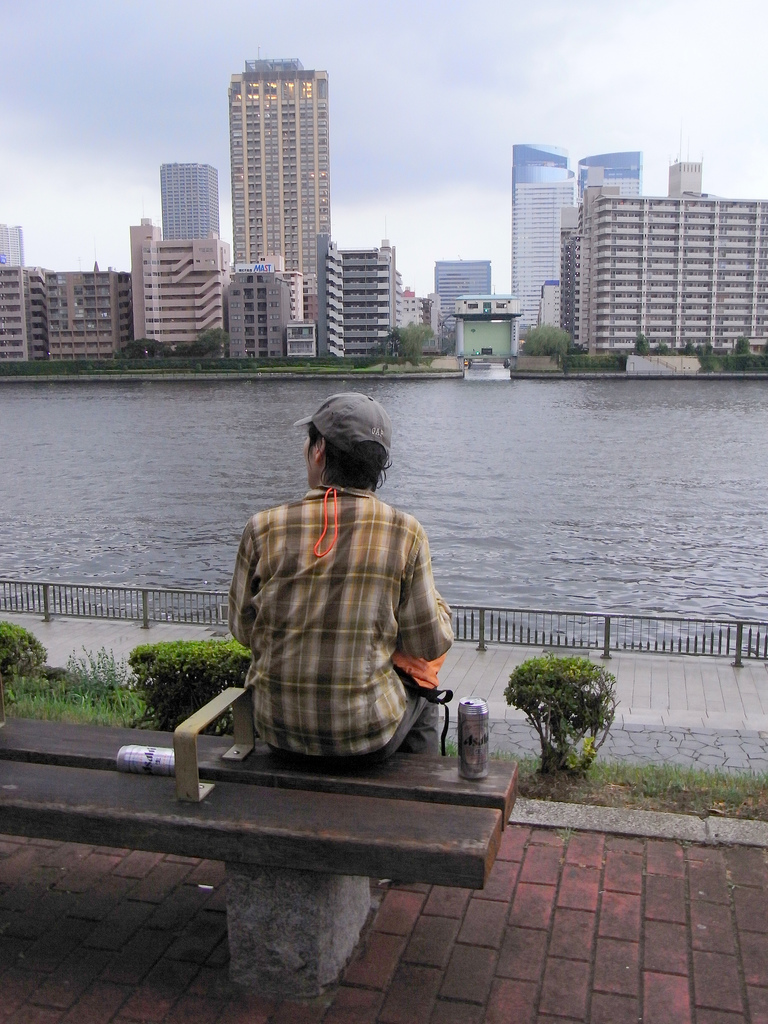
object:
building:
[226, 57, 328, 353]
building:
[132, 225, 224, 351]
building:
[223, 260, 305, 366]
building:
[284, 328, 319, 356]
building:
[511, 139, 575, 328]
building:
[347, 238, 426, 370]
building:
[428, 258, 497, 354]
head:
[289, 403, 393, 491]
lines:
[582, 877, 608, 986]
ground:
[4, 618, 765, 1023]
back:
[233, 488, 448, 761]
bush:
[507, 644, 616, 775]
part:
[229, 865, 376, 994]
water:
[2, 369, 766, 645]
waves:
[492, 485, 766, 620]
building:
[324, 233, 406, 362]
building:
[561, 121, 761, 362]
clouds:
[370, 43, 499, 142]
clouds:
[65, 54, 173, 156]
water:
[518, 413, 657, 589]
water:
[481, 416, 568, 523]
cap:
[295, 389, 400, 469]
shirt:
[232, 496, 443, 767]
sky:
[434, 36, 560, 124]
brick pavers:
[546, 893, 598, 964]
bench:
[2, 703, 518, 958]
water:
[483, 416, 608, 511]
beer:
[454, 692, 489, 780]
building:
[459, 288, 522, 362]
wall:
[284, 214, 348, 301]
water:
[445, 329, 680, 573]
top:
[230, 54, 330, 142]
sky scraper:
[159, 164, 219, 348]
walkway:
[41, 893, 582, 1017]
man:
[223, 391, 449, 750]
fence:
[609, 613, 765, 662]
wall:
[243, 50, 279, 208]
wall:
[277, 93, 303, 269]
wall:
[608, 233, 625, 342]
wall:
[347, 263, 379, 365]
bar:
[173, 666, 251, 798]